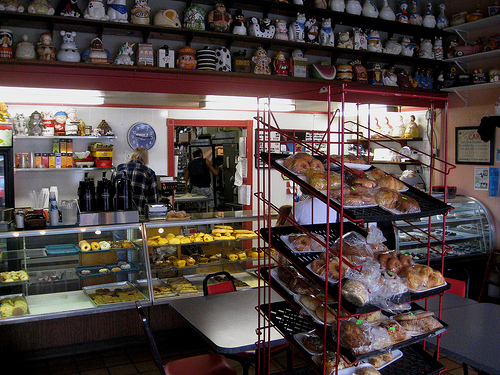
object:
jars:
[422, 3, 437, 28]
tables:
[415, 289, 497, 369]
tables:
[166, 286, 288, 356]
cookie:
[168, 237, 180, 245]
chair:
[138, 314, 239, 375]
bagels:
[302, 167, 344, 189]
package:
[0, 29, 15, 61]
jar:
[115, 43, 135, 65]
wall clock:
[126, 120, 157, 153]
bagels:
[277, 149, 332, 174]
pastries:
[396, 195, 419, 214]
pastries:
[374, 187, 394, 209]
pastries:
[379, 174, 403, 191]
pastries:
[356, 191, 374, 205]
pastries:
[336, 193, 363, 208]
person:
[109, 147, 161, 282]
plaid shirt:
[109, 159, 160, 216]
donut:
[329, 257, 348, 278]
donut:
[312, 260, 327, 274]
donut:
[313, 158, 323, 170]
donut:
[294, 159, 310, 172]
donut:
[297, 235, 312, 252]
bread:
[407, 267, 446, 293]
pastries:
[414, 315, 442, 331]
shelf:
[0, 214, 279, 327]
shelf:
[0, 0, 465, 108]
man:
[182, 146, 220, 212]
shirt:
[185, 158, 213, 188]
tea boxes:
[16, 140, 74, 169]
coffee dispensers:
[77, 166, 132, 213]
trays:
[258, 221, 403, 317]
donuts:
[290, 227, 313, 252]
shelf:
[253, 84, 471, 374]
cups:
[48, 191, 61, 228]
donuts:
[212, 223, 234, 238]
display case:
[0, 193, 499, 329]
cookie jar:
[311, 62, 337, 80]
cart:
[265, 131, 434, 375]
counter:
[0, 195, 498, 326]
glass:
[37, 237, 67, 271]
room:
[175, 125, 243, 210]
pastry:
[78, 240, 91, 254]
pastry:
[167, 236, 182, 244]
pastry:
[226, 252, 239, 263]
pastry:
[89, 240, 101, 250]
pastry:
[98, 240, 110, 251]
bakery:
[0, 0, 500, 375]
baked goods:
[276, 146, 447, 374]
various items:
[2, 3, 402, 82]